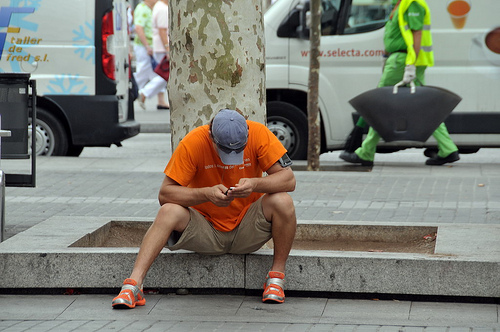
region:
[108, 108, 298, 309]
man is sitting on curb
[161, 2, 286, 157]
tree trunk us behind ban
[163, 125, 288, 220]
man is wearing orange shirt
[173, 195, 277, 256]
man is wearing khaki shorts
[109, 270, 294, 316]
man is wearing orange shoes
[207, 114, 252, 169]
man is wearing blue cap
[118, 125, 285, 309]
the man's shoes match his shirt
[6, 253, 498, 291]
curb is grey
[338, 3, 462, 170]
a man is walking behind the sitting man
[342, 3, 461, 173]
walking man is wearing green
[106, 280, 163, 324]
sneakers are orange and grey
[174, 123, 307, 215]
he has an orange shirt on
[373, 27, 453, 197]
he has a green uniform on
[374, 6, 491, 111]
he has a reflector vest on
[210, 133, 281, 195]
there are sunglasses on his hat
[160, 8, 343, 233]
there is a tree behind the man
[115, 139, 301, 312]
he is sitting on the curb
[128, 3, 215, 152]
passer bys walking behind truck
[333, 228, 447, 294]
dirt area for the tree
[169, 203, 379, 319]
he has khaki shorts on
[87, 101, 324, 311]
Man wearing an orange shirt.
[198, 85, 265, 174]
Grey Nike hat on the man's head.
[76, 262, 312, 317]
Silver and orange sneakers on the man's feet.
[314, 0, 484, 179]
Man wearing green and a safety vest.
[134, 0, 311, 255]
Tree behind the sitting man.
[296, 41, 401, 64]
www.selecta.com on van on the right.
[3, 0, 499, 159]
Two vans beside the road.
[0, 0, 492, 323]
Photo was takin during the day.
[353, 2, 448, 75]
Safety vest on the man to the right.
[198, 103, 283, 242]
Man is looking down at his hands.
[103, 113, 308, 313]
this is a man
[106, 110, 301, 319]
the man is sitted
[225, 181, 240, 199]
the man is holding a cell phone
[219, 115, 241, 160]
the man is wearing a cap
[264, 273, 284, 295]
the shoe is orange in color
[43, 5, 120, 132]
this is a vehicle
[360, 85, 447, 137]
the man is carrying a bag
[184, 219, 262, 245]
the man is wearing shorts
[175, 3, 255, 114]
a tree is behind the man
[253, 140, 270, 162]
the shirt is orange in color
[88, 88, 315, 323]
man sitting on curb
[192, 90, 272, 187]
man wearing glasses on cap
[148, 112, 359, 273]
man wearing orange shirt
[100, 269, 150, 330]
man wearing silver and orange shoes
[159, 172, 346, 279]
man wearing khaki shorts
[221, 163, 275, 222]
man on cellphone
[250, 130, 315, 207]
man wearing ipod on arms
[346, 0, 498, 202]
man dressed in green uniform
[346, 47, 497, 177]
man holding black bag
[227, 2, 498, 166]
white van parked